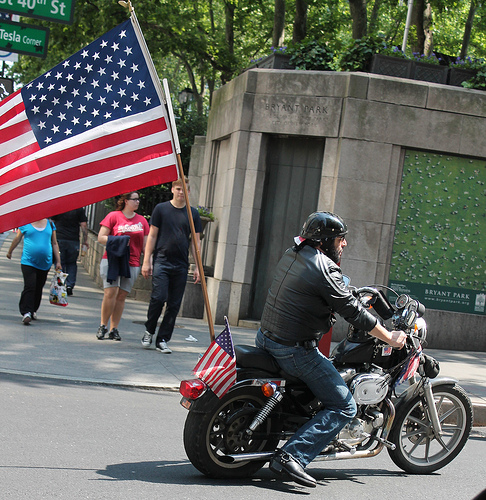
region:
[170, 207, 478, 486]
man riding motrocycle on the road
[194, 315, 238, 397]
small american flag on motorcycle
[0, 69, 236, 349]
large american flag on motorcycle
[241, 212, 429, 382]
man waring black motorcycle helmet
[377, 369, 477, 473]
front wheel of motorcycle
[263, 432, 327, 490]
black leather boots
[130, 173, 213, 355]
man wearing black t-shirt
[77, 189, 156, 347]
woman wearing red shirt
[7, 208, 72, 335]
person wearing blue shirt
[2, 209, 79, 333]
person holding plastic bag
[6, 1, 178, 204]
large american flag on pole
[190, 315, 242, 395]
small american flag on pole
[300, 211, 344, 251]
hard helmet on biker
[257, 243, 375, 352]
black leather jacket on biker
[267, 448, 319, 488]
black steel toed boots on biker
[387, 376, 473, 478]
front wheel on motorcycle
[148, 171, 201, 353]
man all in black walking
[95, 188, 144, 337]
woman in red t-shirt walking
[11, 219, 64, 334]
pregnant woman in blue shirt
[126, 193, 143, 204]
glasses on woman's face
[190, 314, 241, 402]
The small American flag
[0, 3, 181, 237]
The large American flag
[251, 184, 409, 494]
The man on the motorcycle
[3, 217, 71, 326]
The pregnant woman in blue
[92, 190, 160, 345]
The woman in red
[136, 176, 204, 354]
The man in all black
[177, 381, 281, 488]
The back tire of the motorcycle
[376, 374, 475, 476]
The front tire of the motorcycle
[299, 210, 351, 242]
The helmet of the motorcycle rider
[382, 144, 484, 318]
The large green picture on the wall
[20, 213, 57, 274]
Pregnant women in blue blouse.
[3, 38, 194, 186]
Large American Flag.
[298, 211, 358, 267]
Man wearing helmet.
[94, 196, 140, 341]
Lady carrying a dark blue jacket.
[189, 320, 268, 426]
Small American flag on motorcycle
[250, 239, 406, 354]
Man wearing a black leather jacket.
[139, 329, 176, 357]
Pair of black and white tennis shoes.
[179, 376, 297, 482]
Back tire of motorcycle.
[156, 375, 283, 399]
Red lights on motorcycle.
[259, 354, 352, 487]
Man wearing blue jeans and boots.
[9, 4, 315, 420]
two American flags tied to the motorcycle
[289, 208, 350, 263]
the man in the helmet has a beard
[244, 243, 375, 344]
the rider is wearing a leather jacket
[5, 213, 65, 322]
the lady walking is pregnant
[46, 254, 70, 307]
the lady is carrying a shopping bag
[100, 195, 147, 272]
the girl has a red t-shirt on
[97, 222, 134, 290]
a sweater in on the woman's arm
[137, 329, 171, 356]
the boy is wearing sneakers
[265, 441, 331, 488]
the man has black leather boots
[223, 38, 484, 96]
boxes with plants are on the building